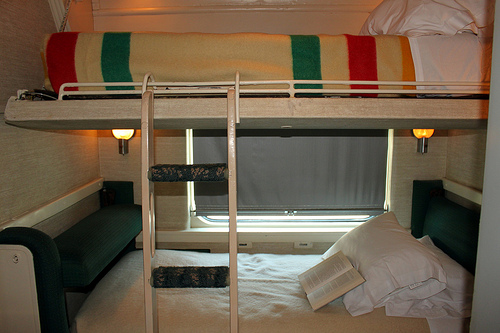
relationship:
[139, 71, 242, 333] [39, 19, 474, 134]
ladder on side of bed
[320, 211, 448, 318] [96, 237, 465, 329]
pillow on bed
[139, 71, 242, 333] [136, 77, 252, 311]
ladder on ladder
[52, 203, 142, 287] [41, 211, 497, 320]
cushion on bed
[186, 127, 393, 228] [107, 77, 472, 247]
window on wall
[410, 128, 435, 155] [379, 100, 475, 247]
light on wall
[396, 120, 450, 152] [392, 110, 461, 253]
light in corner of cabin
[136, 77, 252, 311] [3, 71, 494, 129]
ladder to bed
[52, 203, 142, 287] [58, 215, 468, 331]
cushion on bed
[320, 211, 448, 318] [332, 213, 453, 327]
pillow on bed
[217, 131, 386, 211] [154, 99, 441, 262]
shade on window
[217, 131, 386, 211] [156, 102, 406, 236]
shade on window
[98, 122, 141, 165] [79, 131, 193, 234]
light on wall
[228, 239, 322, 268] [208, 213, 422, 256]
outlets on wall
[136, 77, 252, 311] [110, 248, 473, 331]
ladder for a bunk bed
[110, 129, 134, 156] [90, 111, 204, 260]
light on wall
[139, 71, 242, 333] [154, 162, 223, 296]
ladder with steps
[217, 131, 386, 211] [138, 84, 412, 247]
shade on a window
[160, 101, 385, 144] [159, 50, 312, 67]
blanket on a bed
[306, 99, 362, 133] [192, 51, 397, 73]
green color in blanket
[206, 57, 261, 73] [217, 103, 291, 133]
yellow color in blanket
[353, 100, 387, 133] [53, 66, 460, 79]
red color in blanket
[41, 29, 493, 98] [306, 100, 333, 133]
sheet under blanket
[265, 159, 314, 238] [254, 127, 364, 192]
shade on window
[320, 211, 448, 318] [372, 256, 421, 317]
pillow on top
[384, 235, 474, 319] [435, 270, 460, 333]
pillow on bottom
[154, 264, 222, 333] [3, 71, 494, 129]
first step to top bed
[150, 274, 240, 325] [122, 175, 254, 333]
fur on step of a ladder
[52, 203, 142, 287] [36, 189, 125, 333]
cushion in a train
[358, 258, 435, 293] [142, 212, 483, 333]
pillow on a bed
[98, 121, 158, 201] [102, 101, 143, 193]
yellow light fixture on wall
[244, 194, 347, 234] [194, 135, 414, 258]
blind on window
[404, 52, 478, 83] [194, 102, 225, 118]
sheet on a bed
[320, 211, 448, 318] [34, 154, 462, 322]
pillow on bed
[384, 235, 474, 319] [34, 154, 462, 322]
pillow on bed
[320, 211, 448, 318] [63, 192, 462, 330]
pillow on bed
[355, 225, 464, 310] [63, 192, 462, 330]
pillow on bed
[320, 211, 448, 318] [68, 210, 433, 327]
pillow on bed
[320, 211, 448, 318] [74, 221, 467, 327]
pillow on bed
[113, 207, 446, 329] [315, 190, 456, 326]
bed with pillows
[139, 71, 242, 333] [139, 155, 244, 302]
ladder with steps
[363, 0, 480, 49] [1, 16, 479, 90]
pillow on bed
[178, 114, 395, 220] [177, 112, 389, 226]
curtain over window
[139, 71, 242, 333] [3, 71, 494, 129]
ladder leading to bed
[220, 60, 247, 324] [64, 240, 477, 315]
pole next to bed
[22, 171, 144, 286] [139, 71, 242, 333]
cushion near ladder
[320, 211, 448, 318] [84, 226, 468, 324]
pillow on bed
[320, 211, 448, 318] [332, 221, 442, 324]
pillow on pillow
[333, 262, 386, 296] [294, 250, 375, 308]
corner of book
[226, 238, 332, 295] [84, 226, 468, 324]
light hitting bed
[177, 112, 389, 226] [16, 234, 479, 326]
window next to bed